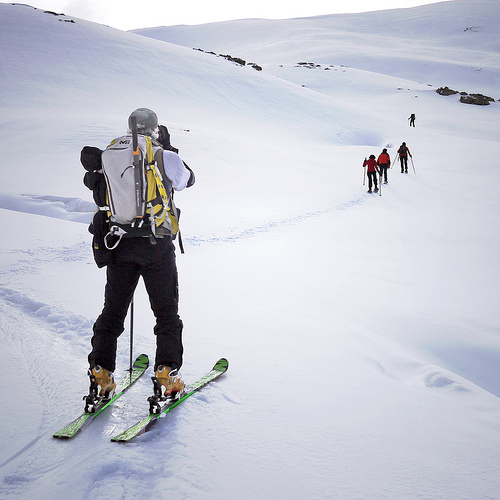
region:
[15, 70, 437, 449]
People walking with skiis on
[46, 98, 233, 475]
Man wearing green skiis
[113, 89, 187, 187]
Man is holding his hands to his face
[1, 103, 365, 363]
Tracks in the snow from people walking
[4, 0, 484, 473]
Snow covered mountains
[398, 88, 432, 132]
Person walking ahead alone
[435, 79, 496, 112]
Rocks sticking out of the snow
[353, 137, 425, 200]
Three people walking while wearing skiis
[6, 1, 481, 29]
Clear cloudless sky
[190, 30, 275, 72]
Rocks showing through the snow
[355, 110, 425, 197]
skiers on a snowy trail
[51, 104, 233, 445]
Skier taking photos of skiers on the trail ahead of him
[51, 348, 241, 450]
downhill skiboots, bindings and skis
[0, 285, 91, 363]
tracks in the snow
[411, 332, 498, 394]
snow gully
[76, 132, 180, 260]
alpine backpack with climbing gear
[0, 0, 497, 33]
white sky with no discernible features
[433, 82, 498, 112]
rocky outcropping bare of snow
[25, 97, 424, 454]
five skiers ascending an alpine trail on the mountain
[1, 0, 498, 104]
ridges of snow on the ascent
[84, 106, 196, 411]
A person standing on skis with his right hand to his face.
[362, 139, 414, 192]
Three people skiing in a row.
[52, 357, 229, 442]
Green and black skis on a man who is stopped.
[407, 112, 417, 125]
The silhouette of a skier all the way in front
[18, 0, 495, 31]
A white sky above the snow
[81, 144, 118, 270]
Three black packs down a man's left side.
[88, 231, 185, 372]
Black pants on a skier who is stopped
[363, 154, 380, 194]
A woman in red behind two other people in a row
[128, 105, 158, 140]
Grey helmet on a man's head who is stopped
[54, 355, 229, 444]
Green and black skis on a man who is stopped in the snow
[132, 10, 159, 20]
this is the sky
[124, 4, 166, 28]
the sky is full of clouds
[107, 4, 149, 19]
the clouds are white in color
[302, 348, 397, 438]
this is the ground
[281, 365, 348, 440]
the ground is full of snow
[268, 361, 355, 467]
the snow is white in color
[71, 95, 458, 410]
these are some people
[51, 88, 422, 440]
the people are snowskating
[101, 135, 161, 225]
this is a bag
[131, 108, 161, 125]
the hat is grey in color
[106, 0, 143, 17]
this is the sky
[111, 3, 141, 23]
the sky is bright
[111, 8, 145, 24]
the sky has some clouds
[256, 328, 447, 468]
this is the ground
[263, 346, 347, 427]
the ground has snow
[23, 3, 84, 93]
this is a mountain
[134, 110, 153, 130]
the cap is grey in color